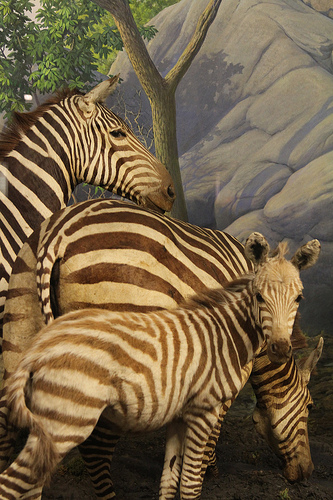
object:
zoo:
[0, 0, 333, 500]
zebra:
[0, 228, 318, 500]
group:
[0, 74, 327, 500]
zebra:
[0, 190, 325, 486]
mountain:
[82, 0, 333, 305]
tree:
[87, 2, 225, 224]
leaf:
[77, 81, 84, 89]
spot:
[169, 453, 177, 473]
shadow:
[105, 21, 234, 142]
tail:
[3, 342, 62, 485]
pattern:
[160, 330, 175, 398]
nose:
[163, 177, 176, 202]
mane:
[177, 272, 257, 310]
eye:
[255, 292, 266, 303]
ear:
[244, 230, 270, 269]